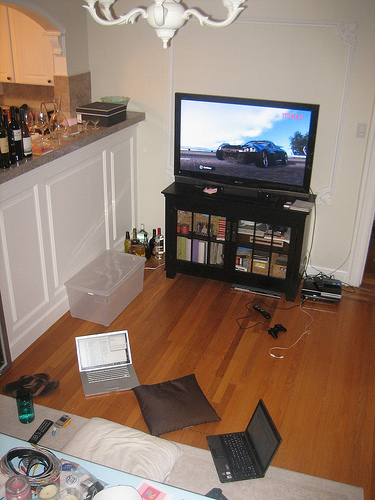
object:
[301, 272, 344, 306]
machine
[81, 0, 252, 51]
lighting fixture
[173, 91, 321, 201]
tv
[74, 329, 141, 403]
laptop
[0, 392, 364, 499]
carpet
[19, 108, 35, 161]
bottles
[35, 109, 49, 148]
glasses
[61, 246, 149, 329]
storage box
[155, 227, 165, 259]
bottles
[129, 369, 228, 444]
pillow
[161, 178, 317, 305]
stand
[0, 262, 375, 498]
floor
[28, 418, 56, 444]
controller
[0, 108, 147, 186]
counter